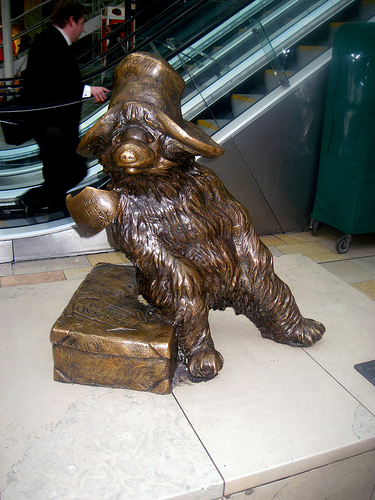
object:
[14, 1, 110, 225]
man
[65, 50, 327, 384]
statue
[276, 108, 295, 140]
wall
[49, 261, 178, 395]
box